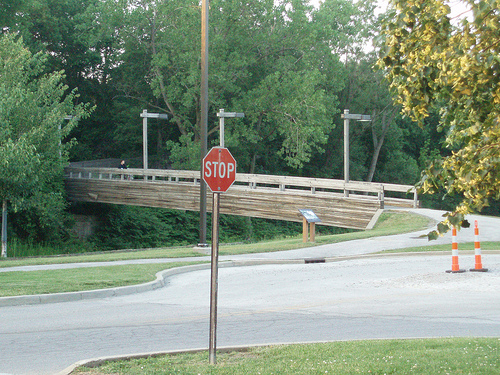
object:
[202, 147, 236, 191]
sign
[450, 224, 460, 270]
cone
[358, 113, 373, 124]
lamp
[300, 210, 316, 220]
plaque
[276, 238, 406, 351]
street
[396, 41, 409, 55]
leave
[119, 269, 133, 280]
grass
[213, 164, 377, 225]
bridge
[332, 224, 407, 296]
road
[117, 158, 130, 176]
person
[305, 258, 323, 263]
sewer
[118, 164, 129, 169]
shrit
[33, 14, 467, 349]
picture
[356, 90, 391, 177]
tree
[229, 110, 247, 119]
light